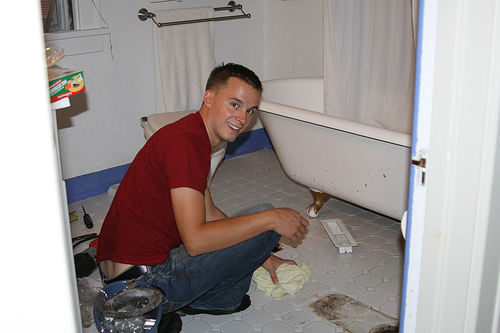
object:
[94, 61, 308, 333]
man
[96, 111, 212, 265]
shirt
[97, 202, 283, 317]
jeans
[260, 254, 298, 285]
hand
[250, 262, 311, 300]
towel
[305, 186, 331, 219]
foot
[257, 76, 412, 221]
tub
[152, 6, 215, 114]
towel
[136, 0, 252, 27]
rod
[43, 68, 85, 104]
box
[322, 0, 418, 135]
shower curtain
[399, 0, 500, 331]
door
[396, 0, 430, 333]
edge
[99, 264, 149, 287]
belt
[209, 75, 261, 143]
face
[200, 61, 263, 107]
hair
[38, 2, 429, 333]
bathroom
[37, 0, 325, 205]
wall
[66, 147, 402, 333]
floor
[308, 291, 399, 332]
dirt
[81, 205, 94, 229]
screwdriver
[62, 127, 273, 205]
baseboard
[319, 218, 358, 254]
air vent